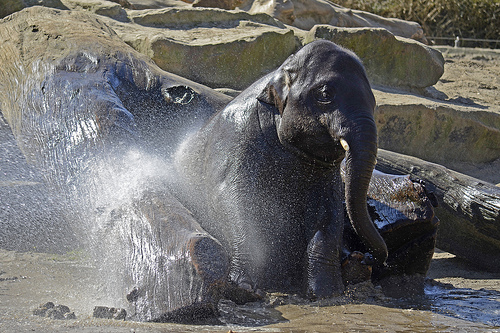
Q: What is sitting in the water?
A: The elephant.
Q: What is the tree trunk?
A: Cut.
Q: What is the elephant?
A: Wet.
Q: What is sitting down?
A: The gray elephant.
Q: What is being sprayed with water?
A: The elephant.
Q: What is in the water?
A: The elephant.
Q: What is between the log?
A: The elephant.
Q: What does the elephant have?
A: Tusks.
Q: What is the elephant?
A: Asian.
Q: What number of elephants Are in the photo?
A: Three.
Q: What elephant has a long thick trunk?
A: The one in the water.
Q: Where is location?
A: In a zoo setting.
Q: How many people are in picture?
A: None.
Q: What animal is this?
A: An elephant.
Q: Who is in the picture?
A: No one.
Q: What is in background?
A: Boulders.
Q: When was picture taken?
A: During daylight.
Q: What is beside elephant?
A: A tree.